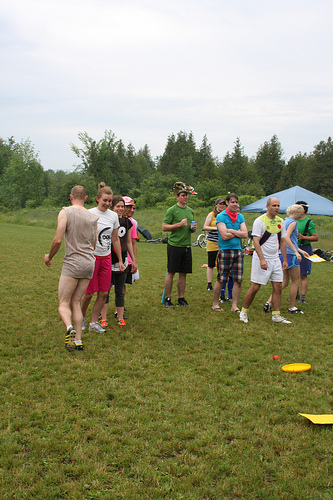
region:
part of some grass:
[201, 349, 248, 385]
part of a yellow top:
[277, 352, 306, 374]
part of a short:
[223, 266, 242, 281]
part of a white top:
[266, 242, 277, 259]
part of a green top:
[178, 230, 194, 241]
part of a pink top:
[95, 266, 106, 279]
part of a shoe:
[162, 299, 176, 309]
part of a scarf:
[226, 214, 236, 223]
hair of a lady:
[94, 182, 109, 193]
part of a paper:
[294, 407, 323, 426]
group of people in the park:
[39, 175, 323, 361]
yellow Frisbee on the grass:
[278, 359, 316, 379]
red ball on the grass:
[267, 353, 282, 362]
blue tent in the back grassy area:
[243, 179, 331, 215]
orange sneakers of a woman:
[96, 315, 133, 330]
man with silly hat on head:
[169, 177, 197, 207]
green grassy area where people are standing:
[14, 364, 282, 490]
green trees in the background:
[11, 125, 332, 185]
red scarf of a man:
[223, 209, 245, 224]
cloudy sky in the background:
[11, 7, 329, 117]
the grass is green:
[98, 395, 252, 460]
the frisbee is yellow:
[269, 359, 330, 386]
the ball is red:
[270, 350, 281, 358]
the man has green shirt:
[158, 200, 196, 248]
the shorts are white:
[249, 257, 286, 281]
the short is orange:
[95, 257, 113, 298]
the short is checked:
[219, 252, 249, 287]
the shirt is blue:
[214, 213, 248, 251]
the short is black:
[166, 243, 206, 277]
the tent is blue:
[265, 186, 332, 211]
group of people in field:
[41, 159, 324, 354]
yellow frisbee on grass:
[278, 358, 315, 380]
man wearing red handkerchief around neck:
[218, 191, 242, 225]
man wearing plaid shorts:
[216, 242, 245, 290]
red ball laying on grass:
[261, 348, 286, 365]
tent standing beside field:
[245, 173, 332, 278]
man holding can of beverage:
[181, 206, 205, 248]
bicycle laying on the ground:
[188, 227, 215, 266]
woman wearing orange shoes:
[98, 309, 135, 335]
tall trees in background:
[53, 130, 329, 224]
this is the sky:
[39, 4, 162, 111]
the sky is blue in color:
[8, 50, 36, 85]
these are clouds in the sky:
[69, 31, 170, 96]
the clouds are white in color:
[83, 38, 117, 72]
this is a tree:
[14, 149, 38, 198]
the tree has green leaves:
[12, 162, 22, 171]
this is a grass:
[138, 354, 209, 424]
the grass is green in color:
[128, 433, 136, 443]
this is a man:
[166, 189, 197, 308]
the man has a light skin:
[166, 225, 175, 229]